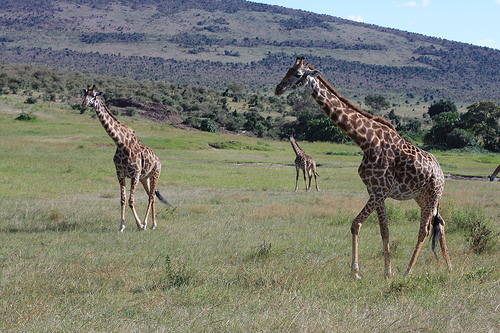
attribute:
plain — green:
[0, 63, 495, 331]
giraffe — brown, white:
[272, 53, 458, 292]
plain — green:
[19, 182, 202, 316]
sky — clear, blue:
[259, 0, 499, 40]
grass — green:
[291, 199, 341, 215]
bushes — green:
[91, 12, 192, 104]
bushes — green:
[171, 90, 238, 129]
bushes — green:
[92, 78, 114, 89]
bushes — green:
[127, 107, 136, 114]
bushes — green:
[152, 91, 175, 105]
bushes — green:
[240, 114, 269, 132]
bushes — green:
[185, 115, 216, 132]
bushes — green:
[72, 27, 146, 45]